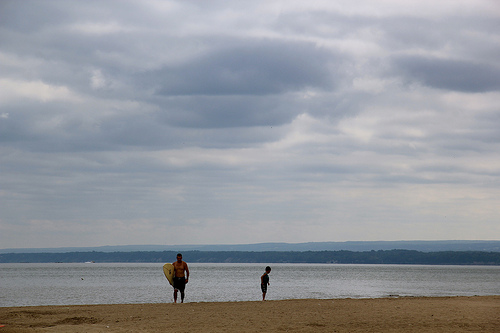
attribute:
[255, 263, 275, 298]
boy — young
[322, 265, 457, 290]
water — calm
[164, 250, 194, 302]
man — shirtless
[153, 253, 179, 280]
surfboard — yellow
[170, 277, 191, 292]
swim trunks — dark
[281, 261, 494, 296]
water — greenish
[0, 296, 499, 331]
beach — Brown 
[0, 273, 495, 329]
beach — deserted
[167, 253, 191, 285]
tank top — tan